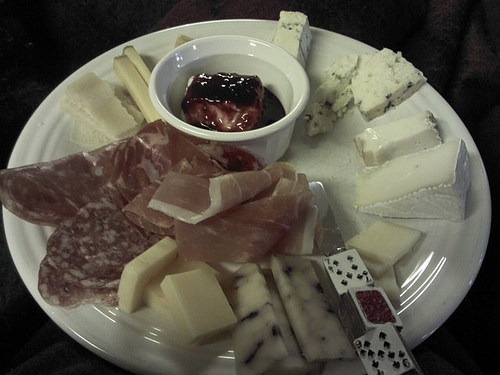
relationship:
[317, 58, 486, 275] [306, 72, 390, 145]
plater holding cheese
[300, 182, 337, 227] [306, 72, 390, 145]
knife for cheese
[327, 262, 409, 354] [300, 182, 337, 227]
handle of knife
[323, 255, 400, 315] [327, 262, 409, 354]
designs on handle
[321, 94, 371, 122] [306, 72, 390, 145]
mold on cheese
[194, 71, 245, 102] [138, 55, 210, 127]
sauce in bowl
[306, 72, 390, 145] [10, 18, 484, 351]
cheese on right side of plate